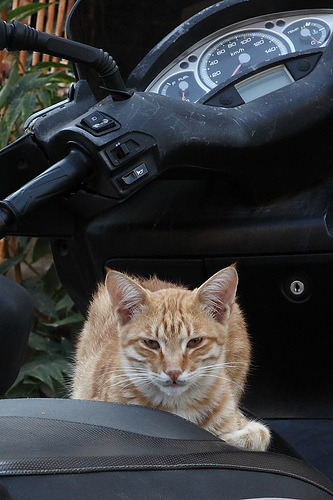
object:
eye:
[140, 338, 161, 354]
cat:
[69, 258, 272, 453]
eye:
[185, 336, 203, 349]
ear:
[104, 267, 152, 332]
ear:
[192, 263, 240, 330]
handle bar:
[0, 14, 332, 243]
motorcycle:
[0, 0, 333, 500]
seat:
[0, 393, 333, 500]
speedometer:
[193, 25, 296, 93]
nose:
[163, 361, 183, 382]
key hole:
[289, 280, 305, 296]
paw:
[221, 421, 271, 453]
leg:
[205, 401, 271, 452]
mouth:
[153, 379, 189, 388]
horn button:
[116, 161, 150, 190]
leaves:
[0, 93, 25, 151]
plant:
[0, 0, 89, 397]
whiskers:
[90, 366, 149, 371]